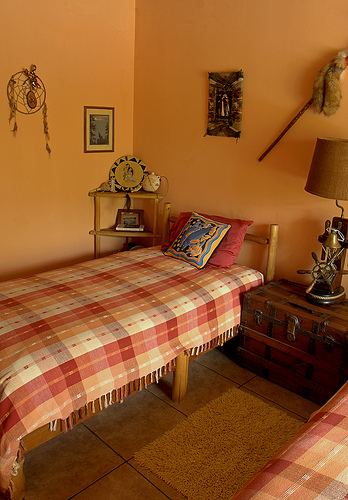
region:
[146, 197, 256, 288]
Two pillows on a bed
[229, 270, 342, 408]
A wooden chest on the floor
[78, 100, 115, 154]
Framed picture on the wall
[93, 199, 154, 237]
Framed photo on a shelf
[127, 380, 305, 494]
White mat on the floor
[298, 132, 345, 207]
A lampshade is brown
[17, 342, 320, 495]
Beige tiles on the floor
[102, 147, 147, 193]
A decorative plate is round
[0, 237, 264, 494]
Colorful quilt on a bed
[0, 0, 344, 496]
A neat and tidy bedroom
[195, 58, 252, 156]
picture on a wall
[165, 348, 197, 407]
leg of a bed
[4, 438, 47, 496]
leg of a bed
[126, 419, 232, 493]
rug on a floor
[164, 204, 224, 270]
pillow on a bed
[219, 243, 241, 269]
pillow on a bed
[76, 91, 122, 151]
picture on a wall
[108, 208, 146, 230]
picture on a shelf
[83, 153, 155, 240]
shelf next to bed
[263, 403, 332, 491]
bed in a room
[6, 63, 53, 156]
dream catcher hung on wall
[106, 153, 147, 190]
native american plate on corner cabinet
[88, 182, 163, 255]
small wooden corner cabinet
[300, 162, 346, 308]
ship theme lamp on trunk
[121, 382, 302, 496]
tan rug on floor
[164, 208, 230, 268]
multi-colored patterned throw pillow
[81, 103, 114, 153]
framed wolf print on wall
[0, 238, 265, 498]
orange, red, and white plaid blanket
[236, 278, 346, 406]
antique trunk between beds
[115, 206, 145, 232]
framed picture on corner cabinet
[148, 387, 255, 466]
a rug on the floor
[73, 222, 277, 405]
a wood twin bed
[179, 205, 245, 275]
two pillows on a bed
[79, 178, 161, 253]
a wood corner shelf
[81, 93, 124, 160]
a picture hanging on a wall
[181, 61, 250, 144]
a framed picture hanging on a wall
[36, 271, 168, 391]
a plaid bed cover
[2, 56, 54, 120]
a dream catcher hanging on a wall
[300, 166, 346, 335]
a lamp on a chest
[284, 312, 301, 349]
a lock on a chest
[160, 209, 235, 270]
pillows on the bed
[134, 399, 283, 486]
rug on the floor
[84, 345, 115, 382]
comforter on the bed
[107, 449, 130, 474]
black lines on the floor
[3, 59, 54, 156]
dream catcher on the wall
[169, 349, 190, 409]
leg of the bed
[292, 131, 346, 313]
ships wheel lamp on the stand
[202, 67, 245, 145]
picture on the wall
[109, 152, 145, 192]
plate on the stand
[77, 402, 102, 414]
fringes on the blanket